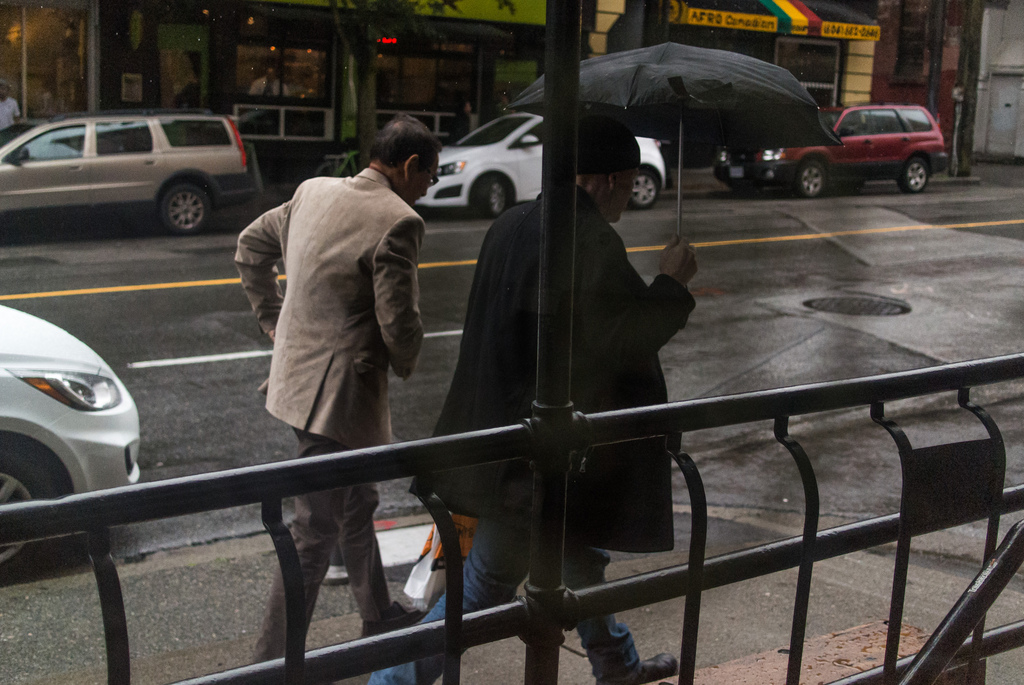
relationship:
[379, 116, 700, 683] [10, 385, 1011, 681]
man on sidewalk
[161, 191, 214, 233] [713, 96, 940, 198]
wheel on suv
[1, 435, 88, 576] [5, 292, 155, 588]
wheel attached to vehicle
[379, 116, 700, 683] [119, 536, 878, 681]
man walking on sidewalk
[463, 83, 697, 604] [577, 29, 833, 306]
man holding umbrella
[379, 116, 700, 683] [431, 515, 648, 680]
man wearing jeans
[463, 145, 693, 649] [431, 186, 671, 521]
man wearing coat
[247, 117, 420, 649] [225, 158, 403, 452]
man wearing blazer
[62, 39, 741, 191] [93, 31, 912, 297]
wall on building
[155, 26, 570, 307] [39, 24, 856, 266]
wall on building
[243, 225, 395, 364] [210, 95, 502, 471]
coat on man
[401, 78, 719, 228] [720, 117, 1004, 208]
car with suv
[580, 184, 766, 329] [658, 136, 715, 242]
hand with pole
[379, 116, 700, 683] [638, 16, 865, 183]
man with umbrella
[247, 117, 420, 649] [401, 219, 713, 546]
man with jacket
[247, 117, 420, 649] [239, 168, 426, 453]
man wearing blazer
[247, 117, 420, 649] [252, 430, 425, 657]
man wearing pants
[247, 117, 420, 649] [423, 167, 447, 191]
man wearing glasses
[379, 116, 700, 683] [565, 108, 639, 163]
man wearing hat